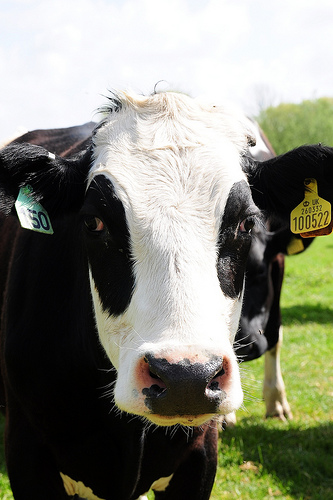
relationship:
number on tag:
[293, 202, 332, 228] [286, 186, 330, 237]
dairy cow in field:
[0, 89, 331, 499] [205, 233, 332, 498]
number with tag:
[293, 202, 332, 228] [285, 176, 332, 233]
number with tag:
[16, 203, 53, 231] [15, 173, 56, 233]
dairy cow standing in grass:
[0, 89, 331, 499] [0, 230, 331, 497]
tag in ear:
[9, 176, 61, 234] [0, 138, 92, 240]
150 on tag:
[20, 203, 50, 229] [10, 178, 56, 235]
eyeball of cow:
[234, 212, 256, 236] [3, 77, 332, 493]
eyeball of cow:
[82, 214, 106, 230] [3, 77, 332, 493]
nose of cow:
[131, 348, 231, 417] [3, 77, 332, 493]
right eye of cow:
[79, 214, 104, 230] [3, 77, 332, 493]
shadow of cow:
[219, 416, 331, 498] [240, 114, 324, 426]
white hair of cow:
[84, 88, 249, 427] [3, 77, 332, 493]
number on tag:
[293, 202, 332, 228] [284, 178, 331, 238]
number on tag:
[293, 202, 332, 228] [278, 171, 331, 235]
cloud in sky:
[17, 3, 101, 49] [0, 0, 330, 151]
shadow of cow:
[219, 416, 331, 498] [41, 99, 276, 219]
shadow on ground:
[219, 416, 331, 498] [0, 231, 331, 498]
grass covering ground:
[272, 235, 330, 366] [265, 228, 331, 373]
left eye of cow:
[232, 216, 256, 237] [13, 89, 301, 420]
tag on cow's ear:
[286, 186, 330, 237] [251, 141, 333, 241]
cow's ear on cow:
[251, 141, 333, 241] [3, 77, 332, 493]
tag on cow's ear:
[286, 186, 330, 237] [257, 141, 326, 202]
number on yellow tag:
[293, 202, 332, 228] [288, 175, 332, 231]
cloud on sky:
[0, 3, 218, 99] [4, 4, 327, 96]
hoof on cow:
[265, 411, 292, 423] [244, 261, 290, 420]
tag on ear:
[9, 176, 61, 234] [2, 135, 92, 232]